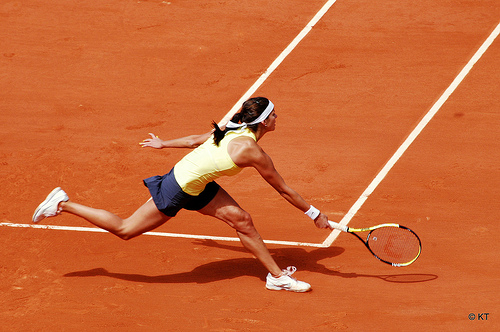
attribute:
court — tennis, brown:
[0, 3, 499, 329]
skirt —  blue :
[138, 162, 228, 222]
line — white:
[277, 32, 303, 49]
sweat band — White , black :
[300, 202, 321, 222]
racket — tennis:
[327, 214, 440, 278]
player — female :
[28, 97, 345, 298]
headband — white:
[228, 98, 272, 137]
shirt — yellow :
[171, 124, 251, 190]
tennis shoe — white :
[25, 184, 72, 222]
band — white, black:
[243, 115, 263, 129]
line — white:
[166, 218, 237, 248]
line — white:
[0, 218, 107, 234]